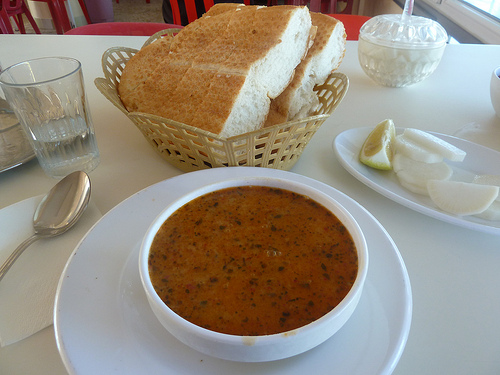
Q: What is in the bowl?
A: Soup.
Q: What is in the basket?
A: Bread.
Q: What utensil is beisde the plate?
A: A spoon.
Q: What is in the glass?
A: A water.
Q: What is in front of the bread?
A: Lemons.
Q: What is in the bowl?
A: Soup.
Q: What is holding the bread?
A: A basket.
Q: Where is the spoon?
A: To the left of the soup.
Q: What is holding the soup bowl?
A: A round, white plate.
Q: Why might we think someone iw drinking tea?
A: There are lemon,or lime, wedges, on a dish.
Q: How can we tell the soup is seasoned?
A: There are flecks, floating in it.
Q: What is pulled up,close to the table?
A: Some red chairs.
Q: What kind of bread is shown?
A: White bread.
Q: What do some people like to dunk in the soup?
A: Bread.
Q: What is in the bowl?
A: Soup.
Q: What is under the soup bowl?
A: A plate.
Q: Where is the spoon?
A: To the left of the plate.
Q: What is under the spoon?
A: A napkin.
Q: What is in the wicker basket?
A: Bread.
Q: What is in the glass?
A: Water.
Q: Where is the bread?
A: In the basket.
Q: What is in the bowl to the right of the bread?
A: Sugar.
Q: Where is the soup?
A: On the table.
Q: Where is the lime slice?
A: To the right of the bread.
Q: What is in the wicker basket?
A: Bread.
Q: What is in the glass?
A: Water.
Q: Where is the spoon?
A: To the left of the plate.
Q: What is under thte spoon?
A: A napkin.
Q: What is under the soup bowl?
A: A white plate.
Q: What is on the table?
A: Soup and bread.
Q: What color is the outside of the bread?
A: Brown.